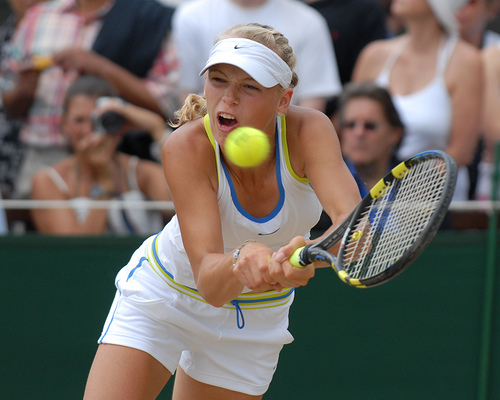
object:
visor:
[198, 36, 294, 92]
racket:
[287, 150, 459, 289]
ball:
[223, 126, 271, 169]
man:
[0, 0, 186, 234]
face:
[340, 96, 395, 164]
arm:
[161, 136, 247, 307]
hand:
[233, 242, 284, 293]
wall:
[62, 240, 119, 315]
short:
[93, 233, 295, 397]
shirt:
[158, 112, 325, 295]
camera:
[91, 96, 128, 136]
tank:
[231, 208, 305, 255]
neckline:
[223, 164, 290, 228]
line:
[203, 113, 236, 198]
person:
[34, 72, 180, 237]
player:
[82, 22, 374, 399]